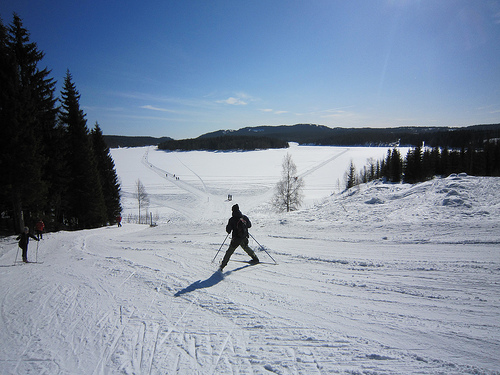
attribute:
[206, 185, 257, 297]
man — skiing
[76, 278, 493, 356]
snow — white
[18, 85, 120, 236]
trees — green, pine, dark, tall, evergreen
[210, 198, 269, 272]
skier — moving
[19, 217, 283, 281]
skiers — group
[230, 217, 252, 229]
jacket — black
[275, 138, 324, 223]
tree — bare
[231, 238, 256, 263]
trousers — dark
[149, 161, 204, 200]
people — distance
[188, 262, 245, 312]
shadow — skier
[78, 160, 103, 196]
leaves — green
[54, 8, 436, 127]
sky — blue, clear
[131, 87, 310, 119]
clouds — puffy, white, wispy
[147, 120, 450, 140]
mountains — distance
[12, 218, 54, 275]
person — skiing, distant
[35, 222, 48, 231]
jacket — red